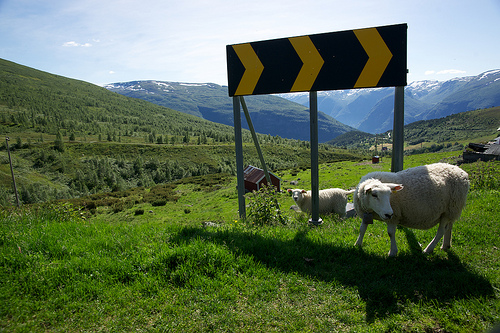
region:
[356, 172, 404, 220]
The white face of the sheep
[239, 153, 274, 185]
The house in the background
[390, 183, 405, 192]
The right ear on the sheep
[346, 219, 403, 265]
The front legs of the sheep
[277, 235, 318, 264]
a shadow on the grass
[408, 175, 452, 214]
the fur on the sheep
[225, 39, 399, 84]
a yellow and black sign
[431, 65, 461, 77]
white cloud in the sky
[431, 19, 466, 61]
the sky is clear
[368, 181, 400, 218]
the head of the sheep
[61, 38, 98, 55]
a cloud in the sky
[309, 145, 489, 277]
this is a sheep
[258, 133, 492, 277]
two sheeps in a field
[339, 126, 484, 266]
sheep has tan fur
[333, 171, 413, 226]
sheeps head is turned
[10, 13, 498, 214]
mountain range in the background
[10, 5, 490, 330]
a bright and clear day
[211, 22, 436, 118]
the sign is yellow and black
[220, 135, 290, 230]
a shack in the field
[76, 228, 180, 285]
green and thick grass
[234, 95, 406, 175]
sign on steel poles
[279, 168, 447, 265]
two sheep around sign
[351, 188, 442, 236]
sheep has white face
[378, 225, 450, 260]
sheep has white legs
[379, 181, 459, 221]
sheep has grey wool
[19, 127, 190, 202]
green trees in valley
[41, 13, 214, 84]
thin clouds in sky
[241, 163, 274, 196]
the building in the distance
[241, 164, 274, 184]
roof on the building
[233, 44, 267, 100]
the arrows are yellow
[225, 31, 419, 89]
arrows on the sign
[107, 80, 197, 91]
snow on the mountains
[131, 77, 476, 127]
mountains in the distance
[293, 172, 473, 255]
the sheep are standing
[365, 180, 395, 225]
the face is white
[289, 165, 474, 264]
Sheep on the field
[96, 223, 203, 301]
Grass on the field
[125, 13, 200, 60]
Blue skies in the background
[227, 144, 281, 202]
A house in the background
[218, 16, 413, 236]
A black and yellow traffic sign.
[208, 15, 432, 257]
A traffic sign in a field.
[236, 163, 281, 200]
A small building lower down the hill.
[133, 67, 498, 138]
Hills in the background.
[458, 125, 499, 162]
A building behind the sheep.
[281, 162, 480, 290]
The sheep stand in the grass.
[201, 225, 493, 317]
A shadow on the ground from the sign.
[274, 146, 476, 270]
a pair of sheeps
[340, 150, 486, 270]
the sheep is tan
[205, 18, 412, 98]
a yellow and black sign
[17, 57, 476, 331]
a large open field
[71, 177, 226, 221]
a patch of weeds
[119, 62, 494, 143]
mountains in the background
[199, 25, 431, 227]
sign on a post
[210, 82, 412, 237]
a set of poles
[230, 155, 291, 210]
a small tin shack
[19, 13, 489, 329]
a bright and sunny day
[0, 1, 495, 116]
the cloudy sky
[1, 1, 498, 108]
A cloudy sky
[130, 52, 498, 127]
The mountain range on the horizon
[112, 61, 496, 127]
A mountain range on the horizon